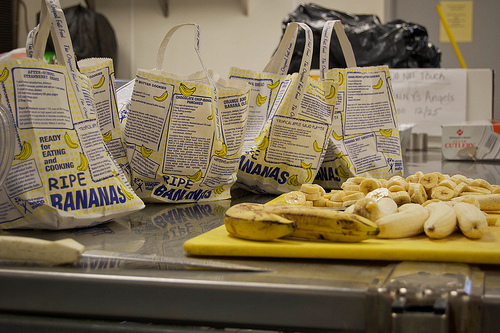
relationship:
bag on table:
[5, 61, 145, 226] [8, 144, 499, 332]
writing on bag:
[48, 188, 126, 206] [5, 61, 145, 226]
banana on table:
[225, 202, 294, 241] [8, 144, 499, 332]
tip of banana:
[288, 219, 299, 232] [225, 202, 294, 241]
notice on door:
[440, 0, 473, 45] [383, 3, 500, 126]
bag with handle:
[5, 61, 145, 226] [27, 1, 78, 68]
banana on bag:
[63, 131, 79, 154] [5, 61, 145, 226]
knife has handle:
[1, 234, 270, 282] [27, 1, 78, 68]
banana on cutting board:
[225, 202, 294, 241] [184, 191, 499, 262]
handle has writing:
[27, 1, 78, 68] [53, 12, 65, 40]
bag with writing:
[5, 61, 145, 226] [48, 188, 126, 206]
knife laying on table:
[1, 234, 270, 282] [8, 144, 499, 332]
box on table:
[442, 125, 499, 164] [8, 144, 499, 332]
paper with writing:
[387, 68, 468, 135] [398, 88, 457, 106]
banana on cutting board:
[427, 201, 455, 241] [184, 191, 499, 262]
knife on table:
[1, 234, 270, 282] [8, 144, 499, 332]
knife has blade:
[1, 234, 270, 282] [86, 249, 271, 278]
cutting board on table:
[184, 191, 499, 262] [8, 144, 499, 332]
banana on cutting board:
[270, 207, 380, 240] [184, 191, 499, 262]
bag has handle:
[5, 61, 145, 226] [27, 1, 78, 68]